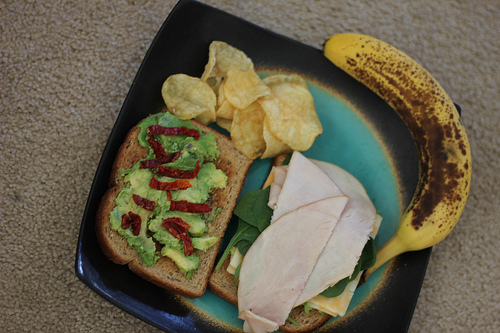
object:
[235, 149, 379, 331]
ham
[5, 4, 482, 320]
floor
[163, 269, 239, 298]
ground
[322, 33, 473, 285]
banana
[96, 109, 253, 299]
slice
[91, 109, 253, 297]
bread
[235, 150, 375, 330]
slice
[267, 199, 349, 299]
turkey meat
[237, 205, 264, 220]
lettuce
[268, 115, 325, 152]
teal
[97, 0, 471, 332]
lunch meat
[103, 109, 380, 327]
toppings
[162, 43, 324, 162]
potato chips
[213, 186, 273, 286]
spinach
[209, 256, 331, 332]
bread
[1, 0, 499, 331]
carpet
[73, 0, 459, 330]
plate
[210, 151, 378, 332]
turkey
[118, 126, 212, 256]
topping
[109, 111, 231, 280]
guacamole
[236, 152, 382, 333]
bacon